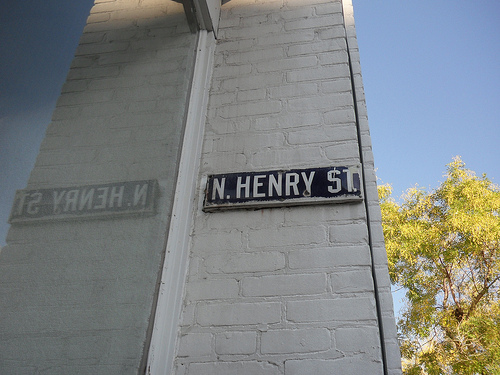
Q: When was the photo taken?
A: Daytime.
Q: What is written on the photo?
A: N. Henry st.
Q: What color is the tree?
A: Green.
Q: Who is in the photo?
A: Nobody.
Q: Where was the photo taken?
A: Near N Henry St.